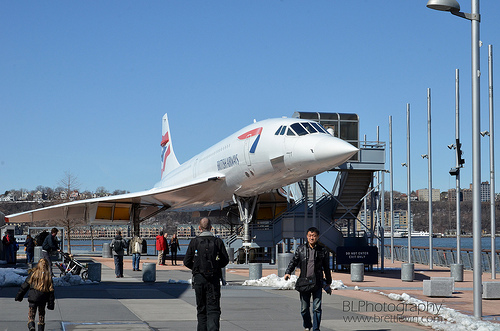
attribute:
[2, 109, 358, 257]
jet — British SST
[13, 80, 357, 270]
airplane — white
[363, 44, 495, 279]
flag poles — empty 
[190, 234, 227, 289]
backpack — black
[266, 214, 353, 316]
jacket — black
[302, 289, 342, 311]
jeans — blue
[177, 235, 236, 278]
coat — black